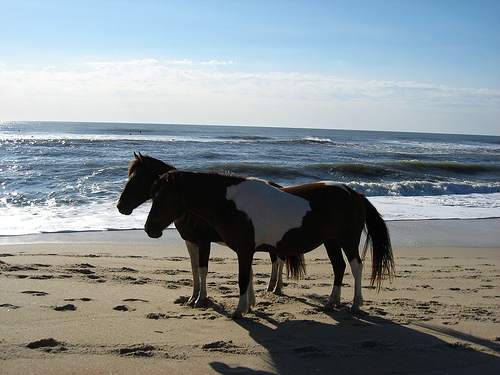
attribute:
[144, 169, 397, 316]
horse — brown, white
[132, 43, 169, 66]
sky — cloudy, av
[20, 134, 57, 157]
water — blue